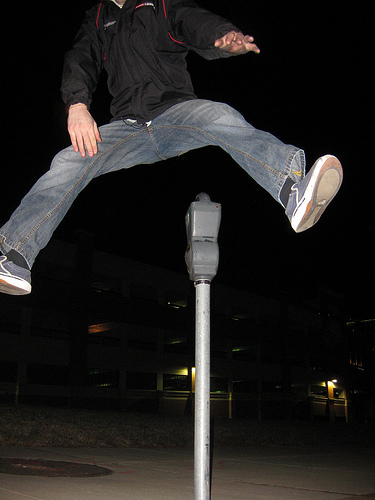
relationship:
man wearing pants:
[0, 0, 349, 292] [0, 103, 306, 268]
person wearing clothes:
[0, 0, 349, 292] [0, 103, 306, 268]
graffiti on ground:
[11, 460, 66, 473] [0, 442, 373, 499]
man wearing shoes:
[0, 0, 349, 292] [0, 153, 345, 299]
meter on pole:
[185, 196, 220, 285] [191, 282, 214, 498]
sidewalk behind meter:
[0, 442, 373, 499] [187, 191, 221, 498]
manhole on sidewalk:
[0, 459, 120, 478] [0, 442, 373, 499]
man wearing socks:
[0, 0, 349, 292] [281, 175, 297, 209]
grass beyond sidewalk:
[3, 412, 374, 446] [0, 442, 373, 499]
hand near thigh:
[215, 33, 261, 54] [167, 103, 244, 158]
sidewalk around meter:
[0, 442, 373, 499] [187, 191, 221, 498]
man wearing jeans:
[0, 0, 349, 292] [0, 103, 306, 268]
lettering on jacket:
[104, 18, 118, 34] [52, 0, 246, 123]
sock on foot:
[281, 175, 297, 209] [283, 157, 343, 240]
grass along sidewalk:
[3, 412, 374, 446] [0, 442, 373, 499]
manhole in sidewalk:
[0, 459, 120, 478] [0, 442, 373, 499]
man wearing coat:
[0, 0, 349, 292] [52, 0, 246, 123]